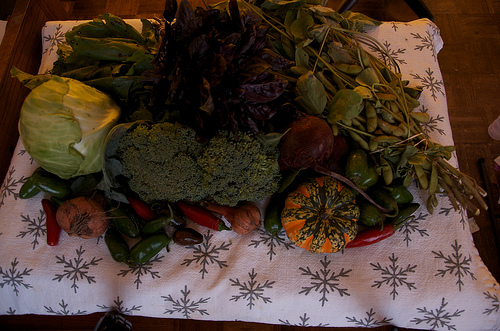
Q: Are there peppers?
A: Yes, there are peppers.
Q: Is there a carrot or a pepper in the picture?
A: Yes, there are peppers.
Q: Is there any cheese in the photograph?
A: No, there is no cheese.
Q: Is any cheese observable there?
A: No, there is no cheese.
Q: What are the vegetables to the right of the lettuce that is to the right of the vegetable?
A: The vegetables are peppers.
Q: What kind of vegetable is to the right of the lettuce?
A: The vegetables are peppers.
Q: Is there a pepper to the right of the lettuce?
A: Yes, there are peppers to the right of the lettuce.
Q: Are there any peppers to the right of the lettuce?
A: Yes, there are peppers to the right of the lettuce.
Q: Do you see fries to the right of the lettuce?
A: No, there are peppers to the right of the lettuce.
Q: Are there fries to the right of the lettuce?
A: No, there are peppers to the right of the lettuce.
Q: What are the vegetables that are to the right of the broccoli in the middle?
A: The vegetables are peppers.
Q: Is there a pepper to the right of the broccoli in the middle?
A: Yes, there are peppers to the right of the broccoli.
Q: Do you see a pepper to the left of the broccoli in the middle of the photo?
A: No, the peppers are to the right of the broccoli.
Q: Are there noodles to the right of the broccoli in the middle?
A: No, there are peppers to the right of the broccoli.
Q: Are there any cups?
A: No, there are no cups.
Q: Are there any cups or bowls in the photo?
A: No, there are no cups or bowls.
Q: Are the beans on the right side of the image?
A: Yes, the beans are on the right of the image.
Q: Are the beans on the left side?
A: No, the beans are on the right of the image.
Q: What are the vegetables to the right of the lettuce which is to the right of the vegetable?
A: The vegetables are beans.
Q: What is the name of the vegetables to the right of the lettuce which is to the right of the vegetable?
A: The vegetables are beans.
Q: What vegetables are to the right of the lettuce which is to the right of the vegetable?
A: The vegetables are beans.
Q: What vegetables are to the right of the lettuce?
A: The vegetables are beans.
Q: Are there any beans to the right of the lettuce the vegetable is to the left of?
A: Yes, there are beans to the right of the lettuce.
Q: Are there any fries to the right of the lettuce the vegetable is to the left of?
A: No, there are beans to the right of the lettuce.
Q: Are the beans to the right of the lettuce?
A: Yes, the beans are to the right of the lettuce.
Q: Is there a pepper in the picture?
A: Yes, there are peppers.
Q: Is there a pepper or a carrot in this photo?
A: Yes, there are peppers.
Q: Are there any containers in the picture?
A: No, there are no containers.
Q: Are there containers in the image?
A: No, there are no containers.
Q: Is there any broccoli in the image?
A: Yes, there is broccoli.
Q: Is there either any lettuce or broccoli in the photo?
A: Yes, there is broccoli.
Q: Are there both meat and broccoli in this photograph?
A: No, there is broccoli but no meat.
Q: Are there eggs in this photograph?
A: No, there are no eggs.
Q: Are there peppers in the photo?
A: Yes, there is a pepper.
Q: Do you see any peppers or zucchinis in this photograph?
A: Yes, there is a pepper.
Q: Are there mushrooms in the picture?
A: No, there are no mushrooms.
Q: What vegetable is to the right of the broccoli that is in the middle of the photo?
A: The vegetable is a pepper.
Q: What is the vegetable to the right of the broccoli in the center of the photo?
A: The vegetable is a pepper.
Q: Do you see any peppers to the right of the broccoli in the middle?
A: Yes, there is a pepper to the right of the broccoli.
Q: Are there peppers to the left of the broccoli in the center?
A: No, the pepper is to the right of the broccoli.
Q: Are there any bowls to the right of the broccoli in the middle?
A: No, there is a pepper to the right of the broccoli.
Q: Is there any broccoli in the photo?
A: Yes, there is broccoli.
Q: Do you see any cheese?
A: No, there is no cheese.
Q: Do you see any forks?
A: No, there are no forks.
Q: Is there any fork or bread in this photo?
A: No, there are no forks or breads.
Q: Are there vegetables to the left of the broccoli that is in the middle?
A: Yes, there is a vegetable to the left of the broccoli.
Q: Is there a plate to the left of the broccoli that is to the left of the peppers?
A: No, there is a vegetable to the left of the broccoli.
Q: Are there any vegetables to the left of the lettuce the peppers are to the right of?
A: Yes, there is a vegetable to the left of the lettuce.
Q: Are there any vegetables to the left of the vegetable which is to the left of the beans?
A: Yes, there is a vegetable to the left of the lettuce.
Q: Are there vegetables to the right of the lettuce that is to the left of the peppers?
A: No, the vegetable is to the left of the lettuce.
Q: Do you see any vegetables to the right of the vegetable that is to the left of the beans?
A: No, the vegetable is to the left of the lettuce.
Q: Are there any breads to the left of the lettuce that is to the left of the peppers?
A: No, there is a vegetable to the left of the lettuce.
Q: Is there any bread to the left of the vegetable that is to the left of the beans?
A: No, there is a vegetable to the left of the lettuce.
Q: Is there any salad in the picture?
A: No, there is no salad.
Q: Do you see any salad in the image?
A: No, there is no salad.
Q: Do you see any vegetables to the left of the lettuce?
A: Yes, there is a vegetable to the left of the lettuce.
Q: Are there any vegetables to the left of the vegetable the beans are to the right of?
A: Yes, there is a vegetable to the left of the lettuce.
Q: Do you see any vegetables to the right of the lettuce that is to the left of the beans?
A: No, the vegetable is to the left of the lettuce.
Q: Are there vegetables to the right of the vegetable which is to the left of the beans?
A: No, the vegetable is to the left of the lettuce.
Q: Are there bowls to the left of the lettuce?
A: No, there is a vegetable to the left of the lettuce.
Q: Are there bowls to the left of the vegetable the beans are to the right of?
A: No, there is a vegetable to the left of the lettuce.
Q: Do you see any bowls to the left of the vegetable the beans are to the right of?
A: No, there is a vegetable to the left of the lettuce.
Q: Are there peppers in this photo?
A: Yes, there are peppers.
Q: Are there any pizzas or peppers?
A: Yes, there are peppers.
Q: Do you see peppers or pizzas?
A: Yes, there are peppers.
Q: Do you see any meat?
A: No, there is no meat.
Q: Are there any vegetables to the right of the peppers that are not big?
A: Yes, there is a vegetable to the right of the peppers.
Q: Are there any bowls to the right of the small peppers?
A: No, there is a vegetable to the right of the peppers.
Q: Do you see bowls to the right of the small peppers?
A: No, there is a vegetable to the right of the peppers.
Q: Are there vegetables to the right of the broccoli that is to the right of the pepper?
A: Yes, there is a vegetable to the right of the broccoli.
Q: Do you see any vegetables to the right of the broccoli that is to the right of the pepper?
A: Yes, there is a vegetable to the right of the broccoli.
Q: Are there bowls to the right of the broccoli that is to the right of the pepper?
A: No, there is a vegetable to the right of the broccoli.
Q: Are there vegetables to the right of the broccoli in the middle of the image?
A: Yes, there is a vegetable to the right of the broccoli.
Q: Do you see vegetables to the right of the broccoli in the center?
A: Yes, there is a vegetable to the right of the broccoli.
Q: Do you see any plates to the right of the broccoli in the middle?
A: No, there is a vegetable to the right of the broccoli.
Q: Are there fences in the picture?
A: No, there are no fences.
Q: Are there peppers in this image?
A: Yes, there is a pepper.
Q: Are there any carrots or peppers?
A: Yes, there is a pepper.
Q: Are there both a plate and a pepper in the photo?
A: No, there is a pepper but no plates.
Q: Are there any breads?
A: No, there are no breads.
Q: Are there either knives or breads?
A: No, there are no breads or knives.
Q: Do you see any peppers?
A: Yes, there is a pepper.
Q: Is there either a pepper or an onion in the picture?
A: Yes, there is a pepper.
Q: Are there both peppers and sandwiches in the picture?
A: No, there is a pepper but no sandwiches.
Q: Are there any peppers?
A: Yes, there is a pepper.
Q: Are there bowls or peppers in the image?
A: Yes, there is a pepper.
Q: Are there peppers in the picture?
A: Yes, there is a pepper.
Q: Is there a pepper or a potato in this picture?
A: Yes, there is a pepper.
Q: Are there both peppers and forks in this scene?
A: No, there is a pepper but no forks.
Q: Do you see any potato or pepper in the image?
A: Yes, there are peppers.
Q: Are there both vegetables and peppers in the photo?
A: Yes, there are both peppers and vegetables.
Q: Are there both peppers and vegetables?
A: Yes, there are both peppers and vegetables.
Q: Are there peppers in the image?
A: Yes, there are peppers.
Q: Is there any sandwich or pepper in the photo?
A: Yes, there are peppers.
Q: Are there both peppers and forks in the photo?
A: No, there are peppers but no forks.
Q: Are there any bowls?
A: No, there are no bowls.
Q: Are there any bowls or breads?
A: No, there are no bowls or breads.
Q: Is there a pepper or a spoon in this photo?
A: Yes, there are peppers.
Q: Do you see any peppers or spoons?
A: Yes, there are peppers.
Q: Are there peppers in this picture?
A: Yes, there are peppers.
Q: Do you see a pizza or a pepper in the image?
A: Yes, there are peppers.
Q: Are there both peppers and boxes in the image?
A: No, there are peppers but no boxes.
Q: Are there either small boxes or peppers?
A: Yes, there are small peppers.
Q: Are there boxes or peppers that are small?
A: Yes, the peppers are small.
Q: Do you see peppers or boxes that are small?
A: Yes, the peppers are small.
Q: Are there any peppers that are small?
A: Yes, there are small peppers.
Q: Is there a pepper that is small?
A: Yes, there are peppers that are small.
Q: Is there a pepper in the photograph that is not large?
A: Yes, there are small peppers.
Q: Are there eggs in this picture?
A: No, there are no eggs.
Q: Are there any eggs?
A: No, there are no eggs.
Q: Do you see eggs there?
A: No, there are no eggs.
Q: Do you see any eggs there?
A: No, there are no eggs.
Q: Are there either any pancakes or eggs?
A: No, there are no eggs or pancakes.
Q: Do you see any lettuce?
A: Yes, there is lettuce.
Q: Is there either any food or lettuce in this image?
A: Yes, there is lettuce.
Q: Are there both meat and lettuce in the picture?
A: No, there is lettuce but no meat.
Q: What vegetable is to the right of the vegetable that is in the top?
A: The vegetable is lettuce.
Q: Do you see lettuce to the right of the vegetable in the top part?
A: Yes, there is lettuce to the right of the vegetable.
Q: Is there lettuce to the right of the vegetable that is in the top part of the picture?
A: Yes, there is lettuce to the right of the vegetable.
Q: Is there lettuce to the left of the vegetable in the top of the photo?
A: No, the lettuce is to the right of the vegetable.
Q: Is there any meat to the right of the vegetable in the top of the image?
A: No, there is lettuce to the right of the vegetable.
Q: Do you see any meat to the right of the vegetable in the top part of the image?
A: No, there is lettuce to the right of the vegetable.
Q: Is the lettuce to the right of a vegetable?
A: Yes, the lettuce is to the right of a vegetable.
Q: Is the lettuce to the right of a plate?
A: No, the lettuce is to the right of a vegetable.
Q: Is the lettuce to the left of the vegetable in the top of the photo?
A: No, the lettuce is to the right of the vegetable.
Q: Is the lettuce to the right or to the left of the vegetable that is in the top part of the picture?
A: The lettuce is to the right of the vegetable.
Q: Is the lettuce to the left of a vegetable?
A: No, the lettuce is to the right of a vegetable.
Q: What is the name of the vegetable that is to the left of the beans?
A: The vegetable is lettuce.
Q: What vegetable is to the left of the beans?
A: The vegetable is lettuce.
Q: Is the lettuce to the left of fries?
A: No, the lettuce is to the left of the beans.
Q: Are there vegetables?
A: Yes, there are vegetables.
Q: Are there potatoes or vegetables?
A: Yes, there are vegetables.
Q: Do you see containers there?
A: No, there are no containers.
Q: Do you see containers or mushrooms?
A: No, there are no containers or mushrooms.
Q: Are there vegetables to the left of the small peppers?
A: Yes, there are vegetables to the left of the peppers.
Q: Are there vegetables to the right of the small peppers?
A: No, the vegetables are to the left of the peppers.